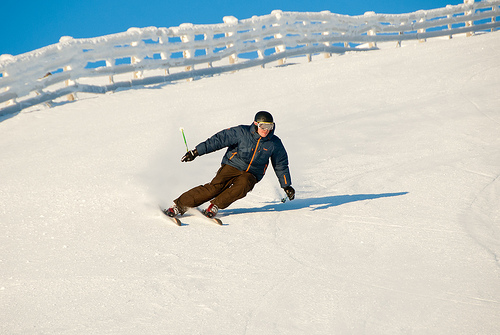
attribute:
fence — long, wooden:
[3, 4, 498, 120]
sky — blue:
[4, 2, 240, 41]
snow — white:
[327, 68, 448, 180]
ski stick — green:
[172, 112, 205, 162]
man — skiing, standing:
[153, 107, 300, 226]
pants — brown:
[167, 165, 261, 217]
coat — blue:
[190, 124, 302, 189]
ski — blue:
[155, 204, 184, 232]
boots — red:
[167, 200, 230, 218]